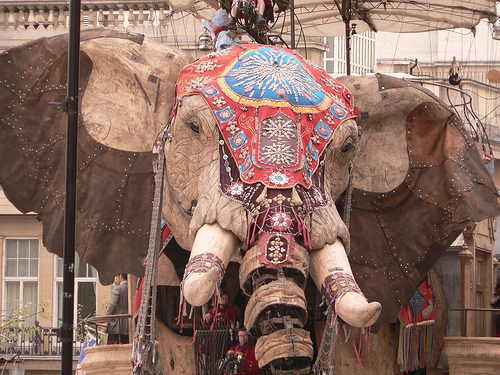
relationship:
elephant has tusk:
[1, 30, 499, 374] [181, 224, 241, 307]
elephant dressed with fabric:
[1, 30, 499, 374] [175, 41, 363, 190]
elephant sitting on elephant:
[1, 27, 500, 370] [1, 30, 499, 374]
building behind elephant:
[0, 0, 500, 374] [1, 30, 499, 374]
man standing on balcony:
[103, 271, 131, 346] [79, 314, 136, 375]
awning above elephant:
[266, 1, 499, 34] [1, 30, 499, 374]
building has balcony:
[0, 0, 500, 374] [0, 1, 175, 49]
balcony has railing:
[0, 321, 84, 363] [1, 320, 62, 355]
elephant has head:
[1, 30, 499, 374] [1, 29, 498, 332]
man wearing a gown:
[190, 7, 243, 51] [200, 17, 241, 52]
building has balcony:
[0, 0, 500, 374] [79, 314, 136, 375]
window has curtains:
[4, 237, 40, 347] [6, 238, 36, 341]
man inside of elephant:
[200, 293, 238, 356] [1, 30, 499, 374]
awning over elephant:
[266, 1, 499, 34] [1, 30, 499, 374]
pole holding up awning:
[341, 18, 356, 78] [266, 1, 499, 34]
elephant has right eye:
[1, 30, 499, 374] [187, 119, 204, 134]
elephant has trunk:
[1, 30, 499, 374] [237, 235, 316, 374]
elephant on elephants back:
[1, 27, 500, 370] [197, 44, 335, 77]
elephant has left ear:
[1, 30, 499, 374] [334, 73, 499, 331]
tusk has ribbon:
[181, 224, 241, 307] [189, 305, 203, 346]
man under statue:
[226, 327, 259, 374] [1, 26, 497, 373]